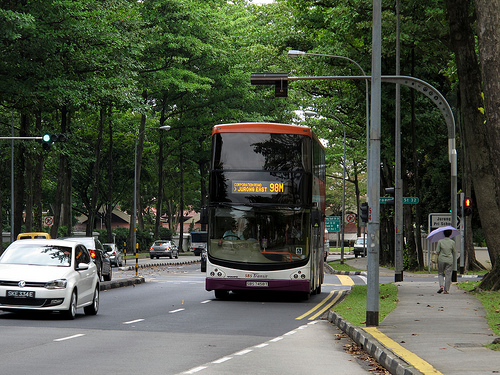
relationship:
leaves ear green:
[166, 27, 225, 87] [70, 30, 94, 59]